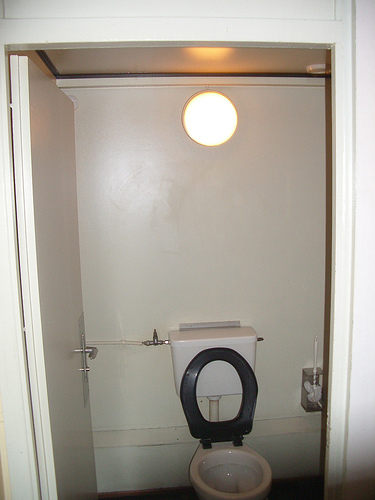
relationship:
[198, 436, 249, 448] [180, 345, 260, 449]
hinges on black seat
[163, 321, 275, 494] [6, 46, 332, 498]
toilet in bathroom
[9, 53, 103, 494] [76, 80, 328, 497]
door in bathroom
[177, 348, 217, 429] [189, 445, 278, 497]
black seat on toilet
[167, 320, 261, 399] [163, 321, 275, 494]
tank on toilet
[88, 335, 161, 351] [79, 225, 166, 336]
pipe on wall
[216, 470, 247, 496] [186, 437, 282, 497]
water in toilet bowl